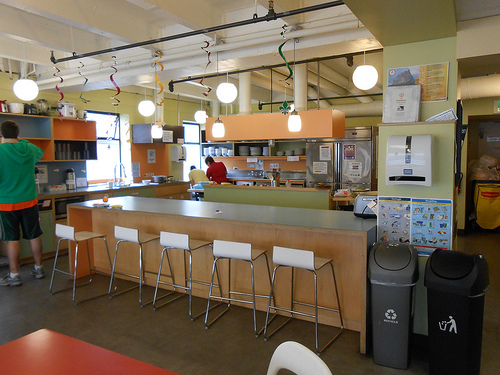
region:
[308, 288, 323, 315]
part of a stand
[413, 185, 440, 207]
part of a chart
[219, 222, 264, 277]
part of a chair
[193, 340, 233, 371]
part of a floor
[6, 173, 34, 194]
part of a jumper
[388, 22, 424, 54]
part of an edge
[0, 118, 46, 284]
Man with green jacket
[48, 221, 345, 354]
Chairs with metal legs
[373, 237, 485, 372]
Garbage cans at the end of the table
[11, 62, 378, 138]
Lights hang from the ceiling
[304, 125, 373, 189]
Refrigerator in the kitchen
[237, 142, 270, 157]
Places on the shelf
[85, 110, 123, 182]
Window on the wall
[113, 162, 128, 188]
Silver faucet over the sink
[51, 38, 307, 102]
Ribbons hang in the air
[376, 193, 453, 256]
Pictures on the wall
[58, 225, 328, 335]
stylish silver stools by the counter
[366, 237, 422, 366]
a black recycle bin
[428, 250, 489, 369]
a black garbage can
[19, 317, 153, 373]
the tip of a red table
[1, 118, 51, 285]
a man wearing a green hoodie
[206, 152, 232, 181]
woman wearing a red shirt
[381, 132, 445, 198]
a wall paper towel holder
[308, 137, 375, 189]
a commercial silvery regrigerator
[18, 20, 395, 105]
light fixtures hanging from the ceiling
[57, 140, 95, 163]
an assortment of bottles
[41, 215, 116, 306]
a low backed chair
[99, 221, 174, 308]
a low backed chair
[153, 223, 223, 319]
a low backed chair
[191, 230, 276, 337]
a low backed chair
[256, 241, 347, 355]
a white low backed chair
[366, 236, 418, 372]
a grey recycling bin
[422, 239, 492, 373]
a black trash can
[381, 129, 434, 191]
a white paper towel dispenser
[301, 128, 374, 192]
two refrigerators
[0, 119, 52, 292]
a man wearing a green hoodie and shorts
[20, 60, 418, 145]
many round lights on ceiling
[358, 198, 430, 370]
one grey recycling can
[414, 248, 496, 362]
one black garbage can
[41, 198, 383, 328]
six white backed bar stools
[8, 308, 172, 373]
red square table in photograph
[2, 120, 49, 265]
man in green shirt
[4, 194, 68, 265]
man in black shorts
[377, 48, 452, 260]
many signs hanging on wall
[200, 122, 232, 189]
person in red shirt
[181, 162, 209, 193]
person in yellow shirt